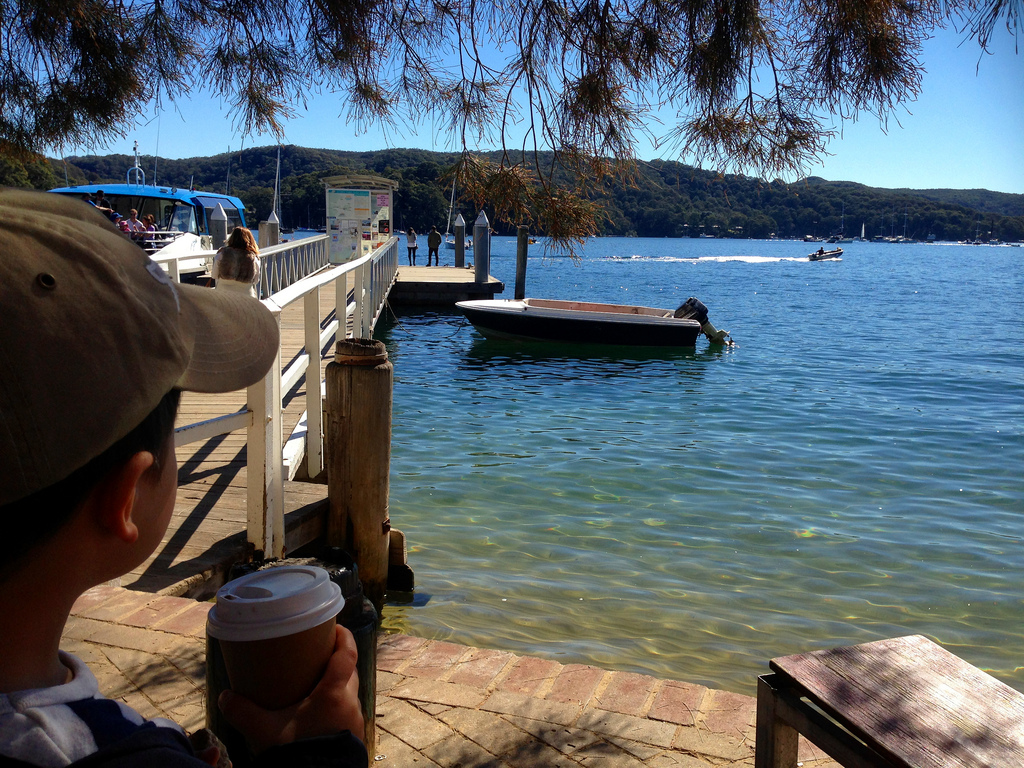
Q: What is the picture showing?
A: It is showing a lake.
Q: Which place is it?
A: It is a lake.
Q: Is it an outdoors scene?
A: Yes, it is outdoors.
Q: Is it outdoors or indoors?
A: It is outdoors.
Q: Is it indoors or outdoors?
A: It is outdoors.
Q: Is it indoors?
A: No, it is outdoors.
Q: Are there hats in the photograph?
A: Yes, there is a hat.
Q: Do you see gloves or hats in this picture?
A: Yes, there is a hat.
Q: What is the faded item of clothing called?
A: The clothing item is a hat.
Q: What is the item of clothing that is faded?
A: The clothing item is a hat.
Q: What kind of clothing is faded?
A: The clothing is a hat.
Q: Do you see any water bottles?
A: No, there are no water bottles.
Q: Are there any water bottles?
A: No, there are no water bottles.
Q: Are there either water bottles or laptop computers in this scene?
A: No, there are no water bottles or laptop computers.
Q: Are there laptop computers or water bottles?
A: No, there are no water bottles or laptop computers.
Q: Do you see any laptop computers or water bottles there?
A: No, there are no water bottles or laptop computers.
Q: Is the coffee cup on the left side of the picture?
A: Yes, the coffee cup is on the left of the image.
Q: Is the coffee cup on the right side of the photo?
A: No, the coffee cup is on the left of the image.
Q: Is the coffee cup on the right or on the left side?
A: The coffee cup is on the left of the image.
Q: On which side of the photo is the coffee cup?
A: The coffee cup is on the left of the image.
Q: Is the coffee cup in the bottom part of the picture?
A: Yes, the coffee cup is in the bottom of the image.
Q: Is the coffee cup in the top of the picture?
A: No, the coffee cup is in the bottom of the image.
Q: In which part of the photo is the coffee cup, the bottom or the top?
A: The coffee cup is in the bottom of the image.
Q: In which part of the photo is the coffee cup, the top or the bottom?
A: The coffee cup is in the bottom of the image.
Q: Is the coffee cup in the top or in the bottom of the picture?
A: The coffee cup is in the bottom of the image.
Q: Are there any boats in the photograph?
A: Yes, there is a boat.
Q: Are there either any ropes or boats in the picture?
A: Yes, there is a boat.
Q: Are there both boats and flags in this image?
A: No, there is a boat but no flags.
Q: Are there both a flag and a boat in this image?
A: No, there is a boat but no flags.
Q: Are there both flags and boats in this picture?
A: No, there is a boat but no flags.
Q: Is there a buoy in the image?
A: No, there are no buoys.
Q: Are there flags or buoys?
A: No, there are no buoys or flags.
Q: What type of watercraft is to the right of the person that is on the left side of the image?
A: The watercraft is a boat.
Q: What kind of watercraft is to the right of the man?
A: The watercraft is a boat.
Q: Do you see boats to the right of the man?
A: Yes, there is a boat to the right of the man.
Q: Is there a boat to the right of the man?
A: Yes, there is a boat to the right of the man.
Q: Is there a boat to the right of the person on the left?
A: Yes, there is a boat to the right of the man.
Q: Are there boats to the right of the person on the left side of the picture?
A: Yes, there is a boat to the right of the man.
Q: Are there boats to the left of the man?
A: No, the boat is to the right of the man.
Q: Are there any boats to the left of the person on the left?
A: No, the boat is to the right of the man.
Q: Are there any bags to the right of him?
A: No, there is a boat to the right of the man.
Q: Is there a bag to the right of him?
A: No, there is a boat to the right of the man.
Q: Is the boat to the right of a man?
A: Yes, the boat is to the right of a man.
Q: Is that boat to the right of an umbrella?
A: No, the boat is to the right of a man.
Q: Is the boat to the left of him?
A: No, the boat is to the right of the man.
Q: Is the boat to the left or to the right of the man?
A: The boat is to the right of the man.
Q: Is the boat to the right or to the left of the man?
A: The boat is to the right of the man.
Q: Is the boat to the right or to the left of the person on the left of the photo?
A: The boat is to the right of the man.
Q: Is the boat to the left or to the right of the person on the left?
A: The boat is to the right of the man.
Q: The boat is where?
A: The boat is in the lake.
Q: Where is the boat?
A: The boat is in the lake.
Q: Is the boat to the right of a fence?
A: Yes, the boat is to the right of a fence.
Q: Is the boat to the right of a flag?
A: No, the boat is to the right of a fence.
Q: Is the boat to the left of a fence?
A: No, the boat is to the right of a fence.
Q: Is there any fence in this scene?
A: Yes, there is a fence.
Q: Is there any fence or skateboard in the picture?
A: Yes, there is a fence.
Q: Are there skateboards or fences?
A: Yes, there is a fence.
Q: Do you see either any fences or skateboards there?
A: Yes, there is a fence.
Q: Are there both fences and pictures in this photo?
A: No, there is a fence but no pictures.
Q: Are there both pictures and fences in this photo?
A: No, there is a fence but no pictures.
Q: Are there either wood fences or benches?
A: Yes, there is a wood fence.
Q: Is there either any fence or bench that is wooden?
A: Yes, the fence is wooden.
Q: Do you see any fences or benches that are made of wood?
A: Yes, the fence is made of wood.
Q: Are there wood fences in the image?
A: Yes, there is a wood fence.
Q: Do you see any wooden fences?
A: Yes, there is a wood fence.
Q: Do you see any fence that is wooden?
A: Yes, there is a fence that is wooden.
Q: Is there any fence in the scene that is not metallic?
A: Yes, there is a wooden fence.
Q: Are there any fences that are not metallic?
A: Yes, there is a wooden fence.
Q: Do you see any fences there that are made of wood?
A: Yes, there is a fence that is made of wood.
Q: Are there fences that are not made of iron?
A: Yes, there is a fence that is made of wood.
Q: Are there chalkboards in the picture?
A: No, there are no chalkboards.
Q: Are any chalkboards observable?
A: No, there are no chalkboards.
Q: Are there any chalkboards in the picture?
A: No, there are no chalkboards.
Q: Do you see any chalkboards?
A: No, there are no chalkboards.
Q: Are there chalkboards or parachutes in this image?
A: No, there are no chalkboards or parachutes.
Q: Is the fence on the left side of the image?
A: Yes, the fence is on the left of the image.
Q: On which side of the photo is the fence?
A: The fence is on the left of the image.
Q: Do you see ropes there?
A: No, there are no ropes.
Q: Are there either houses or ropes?
A: No, there are no ropes or houses.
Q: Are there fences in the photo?
A: Yes, there is a fence.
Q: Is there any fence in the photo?
A: Yes, there is a fence.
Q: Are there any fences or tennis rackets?
A: Yes, there is a fence.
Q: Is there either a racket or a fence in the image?
A: Yes, there is a fence.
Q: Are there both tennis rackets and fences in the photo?
A: No, there is a fence but no rackets.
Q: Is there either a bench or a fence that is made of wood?
A: Yes, the fence is made of wood.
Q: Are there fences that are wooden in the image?
A: Yes, there is a wood fence.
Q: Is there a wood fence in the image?
A: Yes, there is a wood fence.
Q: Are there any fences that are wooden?
A: Yes, there is a fence that is wooden.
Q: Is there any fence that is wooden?
A: Yes, there is a fence that is wooden.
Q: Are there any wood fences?
A: Yes, there is a fence that is made of wood.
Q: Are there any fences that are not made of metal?
A: Yes, there is a fence that is made of wood.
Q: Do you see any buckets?
A: No, there are no buckets.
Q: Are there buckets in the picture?
A: No, there are no buckets.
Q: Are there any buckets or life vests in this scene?
A: No, there are no buckets or life vests.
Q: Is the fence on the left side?
A: Yes, the fence is on the left of the image.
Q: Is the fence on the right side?
A: No, the fence is on the left of the image.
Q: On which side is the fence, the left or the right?
A: The fence is on the left of the image.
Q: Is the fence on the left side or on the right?
A: The fence is on the left of the image.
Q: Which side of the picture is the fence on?
A: The fence is on the left of the image.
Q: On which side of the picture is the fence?
A: The fence is on the left of the image.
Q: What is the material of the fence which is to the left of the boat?
A: The fence is made of wood.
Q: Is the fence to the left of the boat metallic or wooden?
A: The fence is wooden.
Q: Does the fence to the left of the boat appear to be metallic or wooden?
A: The fence is wooden.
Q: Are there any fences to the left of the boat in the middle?
A: Yes, there is a fence to the left of the boat.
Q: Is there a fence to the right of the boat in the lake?
A: No, the fence is to the left of the boat.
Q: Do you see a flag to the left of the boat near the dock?
A: No, there is a fence to the left of the boat.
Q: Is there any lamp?
A: No, there are no lamps.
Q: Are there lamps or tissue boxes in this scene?
A: No, there are no lamps or tissue boxes.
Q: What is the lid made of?
A: The lid is made of plastic.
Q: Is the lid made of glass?
A: No, the lid is made of plastic.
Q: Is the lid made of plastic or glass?
A: The lid is made of plastic.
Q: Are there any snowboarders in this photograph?
A: No, there are no snowboarders.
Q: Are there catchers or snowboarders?
A: No, there are no snowboarders or catchers.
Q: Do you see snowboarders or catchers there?
A: No, there are no snowboarders or catchers.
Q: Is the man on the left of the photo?
A: Yes, the man is on the left of the image.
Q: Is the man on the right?
A: No, the man is on the left of the image.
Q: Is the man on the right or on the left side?
A: The man is on the left of the image.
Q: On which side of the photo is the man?
A: The man is on the left of the image.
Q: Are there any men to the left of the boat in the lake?
A: Yes, there is a man to the left of the boat.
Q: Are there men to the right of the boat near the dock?
A: No, the man is to the left of the boat.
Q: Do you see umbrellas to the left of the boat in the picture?
A: No, there is a man to the left of the boat.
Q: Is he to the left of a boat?
A: Yes, the man is to the left of a boat.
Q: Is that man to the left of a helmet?
A: No, the man is to the left of a boat.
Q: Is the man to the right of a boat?
A: No, the man is to the left of a boat.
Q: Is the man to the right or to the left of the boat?
A: The man is to the left of the boat.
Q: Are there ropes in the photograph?
A: No, there are no ropes.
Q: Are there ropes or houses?
A: No, there are no ropes or houses.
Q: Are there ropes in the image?
A: No, there are no ropes.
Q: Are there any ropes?
A: No, there are no ropes.